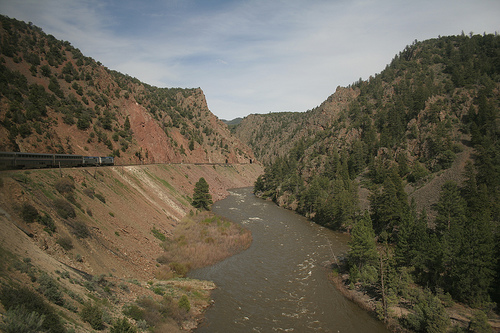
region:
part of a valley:
[273, 129, 293, 170]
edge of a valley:
[187, 173, 202, 198]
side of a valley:
[91, 176, 106, 189]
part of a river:
[255, 249, 278, 278]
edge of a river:
[117, 155, 163, 279]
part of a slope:
[103, 159, 139, 249]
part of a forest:
[442, 232, 468, 266]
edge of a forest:
[373, 105, 383, 117]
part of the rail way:
[125, 153, 136, 164]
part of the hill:
[269, 109, 284, 128]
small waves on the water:
[237, 206, 279, 226]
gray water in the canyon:
[224, 270, 314, 298]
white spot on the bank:
[115, 245, 142, 264]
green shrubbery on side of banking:
[77, 290, 188, 320]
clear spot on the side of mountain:
[121, 163, 187, 215]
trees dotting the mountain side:
[310, 148, 445, 226]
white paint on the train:
[93, 148, 108, 172]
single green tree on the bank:
[186, 165, 228, 220]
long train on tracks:
[31, 145, 128, 167]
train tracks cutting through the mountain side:
[128, 146, 255, 171]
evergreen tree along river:
[175, 174, 213, 218]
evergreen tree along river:
[400, 209, 429, 274]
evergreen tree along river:
[452, 238, 477, 293]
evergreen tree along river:
[284, 177, 301, 210]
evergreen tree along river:
[76, 218, 88, 240]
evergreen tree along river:
[119, 117, 134, 138]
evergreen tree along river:
[452, 248, 493, 298]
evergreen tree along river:
[417, 165, 424, 184]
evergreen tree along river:
[388, 109, 403, 146]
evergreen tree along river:
[347, 140, 369, 172]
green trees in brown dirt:
[408, 41, 470, 102]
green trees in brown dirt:
[335, 113, 386, 167]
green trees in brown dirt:
[402, 157, 452, 208]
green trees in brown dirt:
[303, 160, 360, 217]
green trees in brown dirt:
[23, 77, 101, 135]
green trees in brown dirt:
[42, 186, 113, 228]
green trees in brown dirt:
[172, 101, 222, 135]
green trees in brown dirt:
[258, 119, 309, 154]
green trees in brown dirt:
[272, 163, 342, 211]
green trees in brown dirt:
[416, 57, 491, 88]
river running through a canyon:
[177, 181, 392, 326]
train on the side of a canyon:
[0, 153, 113, 171]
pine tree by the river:
[191, 177, 213, 213]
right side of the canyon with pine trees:
[262, 29, 496, 311]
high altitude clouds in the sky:
[2, 5, 495, 117]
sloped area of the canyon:
[2, 166, 257, 330]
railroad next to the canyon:
[2, 157, 270, 184]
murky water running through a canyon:
[165, 185, 395, 332]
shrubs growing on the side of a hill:
[2, 17, 251, 157]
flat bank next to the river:
[120, 205, 249, 330]